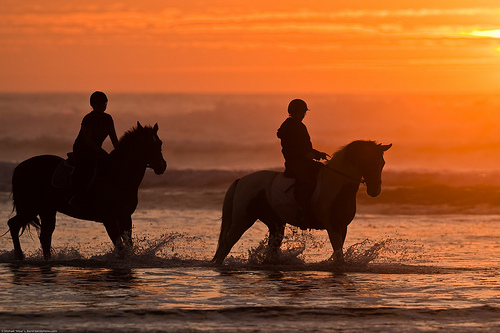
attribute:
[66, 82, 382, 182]
people — riding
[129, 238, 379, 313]
water — splashing, below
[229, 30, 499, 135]
sunset — distant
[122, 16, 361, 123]
sky — above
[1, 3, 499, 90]
sky — dark orange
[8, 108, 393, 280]
horses — walking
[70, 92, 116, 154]
person — one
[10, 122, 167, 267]
horse — one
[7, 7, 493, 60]
clouds — few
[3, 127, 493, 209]
waves — small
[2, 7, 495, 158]
sunset — orange 